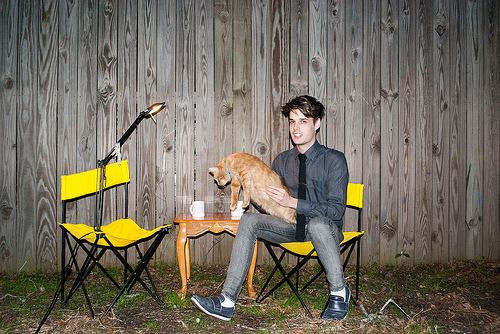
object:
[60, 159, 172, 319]
chair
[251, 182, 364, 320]
chair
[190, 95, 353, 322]
person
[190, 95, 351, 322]
man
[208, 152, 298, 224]
cat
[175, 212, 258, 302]
table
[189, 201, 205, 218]
cup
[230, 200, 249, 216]
cup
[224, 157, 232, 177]
collar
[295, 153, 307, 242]
tie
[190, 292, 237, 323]
shoe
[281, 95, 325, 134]
hair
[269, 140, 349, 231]
shirt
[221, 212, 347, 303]
jeans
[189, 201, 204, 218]
mug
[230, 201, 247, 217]
mug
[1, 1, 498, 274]
fence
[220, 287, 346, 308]
socks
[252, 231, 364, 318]
base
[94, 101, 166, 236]
light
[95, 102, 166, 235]
lamp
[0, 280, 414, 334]
twigs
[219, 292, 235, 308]
sock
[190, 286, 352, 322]
loafers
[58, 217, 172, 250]
seat